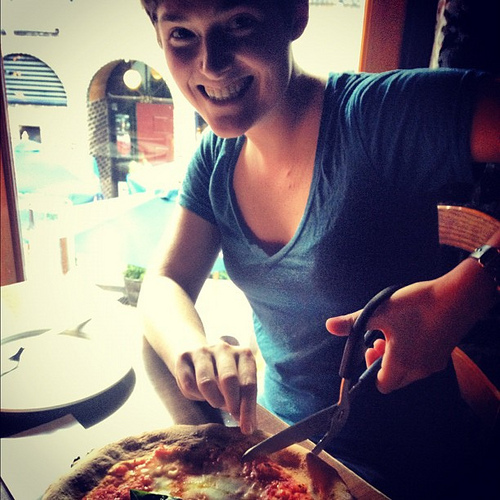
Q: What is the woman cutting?
A: Pizza.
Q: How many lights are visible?
A: One.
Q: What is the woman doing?
A: Cutting a pizza.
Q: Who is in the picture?
A: A woman.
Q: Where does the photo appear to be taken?
A: Pizza place.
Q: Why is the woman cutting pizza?
A: To make slices.